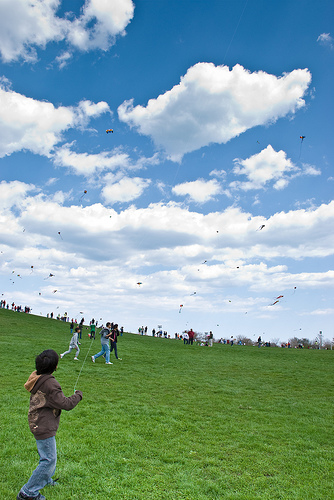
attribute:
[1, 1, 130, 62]
cloud — big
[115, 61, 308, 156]
cloud — big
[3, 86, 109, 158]
cloud — big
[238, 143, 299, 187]
cloud — big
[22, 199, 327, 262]
cloud — big